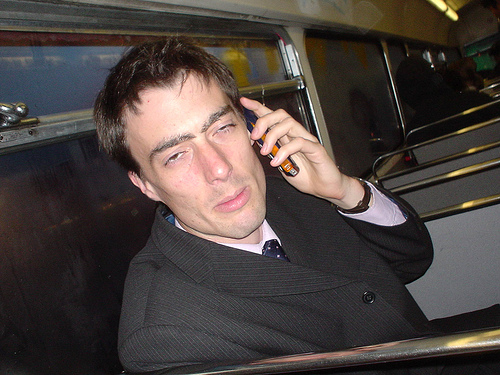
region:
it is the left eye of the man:
[212, 119, 234, 137]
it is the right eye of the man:
[161, 151, 186, 169]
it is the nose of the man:
[204, 154, 231, 184]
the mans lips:
[208, 186, 251, 213]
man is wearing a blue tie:
[260, 240, 294, 258]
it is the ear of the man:
[132, 174, 163, 197]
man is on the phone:
[244, 116, 296, 174]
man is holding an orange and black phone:
[244, 113, 298, 179]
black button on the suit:
[360, 287, 381, 307]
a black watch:
[348, 175, 376, 218]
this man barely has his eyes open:
[37, 33, 431, 373]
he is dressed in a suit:
[118, 200, 410, 366]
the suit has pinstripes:
[141, 226, 297, 372]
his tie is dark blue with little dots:
[266, 233, 291, 269]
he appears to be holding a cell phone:
[246, 99, 309, 204]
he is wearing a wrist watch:
[355, 160, 373, 224]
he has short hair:
[77, 39, 245, 231]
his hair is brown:
[84, 33, 246, 186]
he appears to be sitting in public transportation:
[81, 73, 495, 369]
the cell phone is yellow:
[236, 102, 308, 189]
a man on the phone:
[69, 47, 319, 274]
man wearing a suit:
[125, 179, 464, 371]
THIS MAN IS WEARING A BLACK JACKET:
[105, 162, 440, 372]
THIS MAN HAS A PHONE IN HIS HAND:
[240, 95, 303, 185]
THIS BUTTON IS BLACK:
[358, 282, 381, 312]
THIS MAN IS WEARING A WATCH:
[323, 175, 378, 222]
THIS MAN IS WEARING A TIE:
[251, 235, 294, 263]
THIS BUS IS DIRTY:
[0, 0, 496, 367]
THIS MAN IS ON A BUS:
[85, 17, 450, 372]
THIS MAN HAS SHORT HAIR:
[58, 35, 253, 168]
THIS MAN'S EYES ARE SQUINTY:
[157, 115, 244, 172]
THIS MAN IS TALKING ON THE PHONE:
[72, 31, 444, 373]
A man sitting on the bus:
[71, 35, 461, 374]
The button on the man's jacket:
[350, 280, 382, 312]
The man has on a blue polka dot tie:
[256, 233, 293, 268]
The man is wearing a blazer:
[111, 165, 438, 372]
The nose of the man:
[194, 130, 236, 184]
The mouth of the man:
[207, 178, 269, 216]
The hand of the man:
[238, 90, 348, 204]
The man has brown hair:
[76, 29, 270, 186]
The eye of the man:
[144, 128, 204, 168]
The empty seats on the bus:
[403, 125, 498, 272]